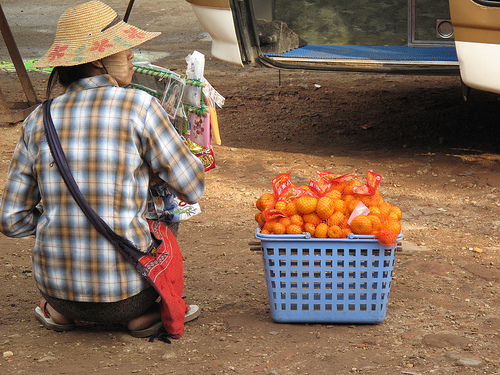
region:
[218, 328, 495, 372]
The ground is the color brown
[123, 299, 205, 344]
The feet of the woman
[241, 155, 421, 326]
The basket has oranges on it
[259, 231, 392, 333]
The color of the basket is blue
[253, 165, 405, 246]
The oranges are the color orange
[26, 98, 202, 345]
The woman is wearing a bag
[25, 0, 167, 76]
The woman is wearing a hat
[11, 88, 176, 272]
The woman is wearing a plaid shirt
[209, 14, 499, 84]
A van is on the ground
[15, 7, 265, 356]
The woman is sitting on the ground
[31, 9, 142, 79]
THAT IS A HAT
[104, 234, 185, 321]
THAT IS A BAG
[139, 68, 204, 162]
THAT IS MERCHANDISE THE PERSON IS SELLING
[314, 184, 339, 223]
THAT IS\AN ORANGE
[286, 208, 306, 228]
THAT IS\AN ORANGE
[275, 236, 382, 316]
THAT IS A FRUIT BASKET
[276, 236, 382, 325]
THE FRUIT BASKET IS BLUE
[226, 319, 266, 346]
THIS IS THE GROUND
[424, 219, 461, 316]
THIS IS THE GROUND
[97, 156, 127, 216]
THE PERSON IS WEARING A CHECKED SHIRT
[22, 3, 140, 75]
A woman is wearing a hat.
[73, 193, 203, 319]
A woman is carrying a red bag.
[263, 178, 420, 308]
Tangerines are in a basket.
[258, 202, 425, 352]
A basket is carring tangerines.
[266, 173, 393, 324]
A basket is carrying orange fruit.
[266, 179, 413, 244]
Tangerines are in a red net.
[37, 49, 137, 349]
A woman is sitting on a ground.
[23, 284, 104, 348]
A woman is wearing filp flops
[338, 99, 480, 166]
Rocks are under a car.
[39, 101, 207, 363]
A red bag is carried by a woman.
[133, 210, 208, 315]
the bag is red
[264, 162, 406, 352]
oranges in blue basket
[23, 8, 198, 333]
a person wearing a straw hat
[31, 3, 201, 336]
a person with a red bag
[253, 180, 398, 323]
a basket of oranges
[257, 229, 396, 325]
a blue basket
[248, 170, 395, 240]
bags of oranges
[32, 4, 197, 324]
a person sitting on the ground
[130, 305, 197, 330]
the flip flop the person is wearing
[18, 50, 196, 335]
a person wearing a plaid shirt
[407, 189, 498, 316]
rocks and dirt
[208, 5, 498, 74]
the back of a car